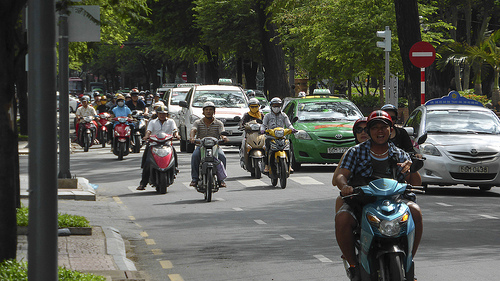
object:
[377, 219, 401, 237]
headlight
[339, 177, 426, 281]
motorcycle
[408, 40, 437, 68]
sign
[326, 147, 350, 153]
license plate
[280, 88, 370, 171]
car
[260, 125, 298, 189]
motorcycle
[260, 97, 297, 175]
person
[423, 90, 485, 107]
sign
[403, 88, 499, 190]
car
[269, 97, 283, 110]
helmet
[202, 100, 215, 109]
helmet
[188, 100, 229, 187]
man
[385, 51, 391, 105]
pole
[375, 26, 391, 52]
light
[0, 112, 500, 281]
road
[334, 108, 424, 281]
person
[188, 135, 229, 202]
motorcycle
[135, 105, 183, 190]
man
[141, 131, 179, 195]
motorcycle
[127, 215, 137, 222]
line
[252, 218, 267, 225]
line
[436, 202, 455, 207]
line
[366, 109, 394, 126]
helmet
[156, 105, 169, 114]
helmet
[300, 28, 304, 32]
leaves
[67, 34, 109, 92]
trees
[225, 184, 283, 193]
shadow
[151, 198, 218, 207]
shadow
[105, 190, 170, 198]
shadow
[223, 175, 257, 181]
shadow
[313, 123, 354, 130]
graphic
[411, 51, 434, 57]
line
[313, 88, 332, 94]
sign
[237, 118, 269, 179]
motorcycle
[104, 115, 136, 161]
motorcycle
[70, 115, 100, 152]
motorcycle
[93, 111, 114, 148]
motorcycle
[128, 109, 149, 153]
motorcycle